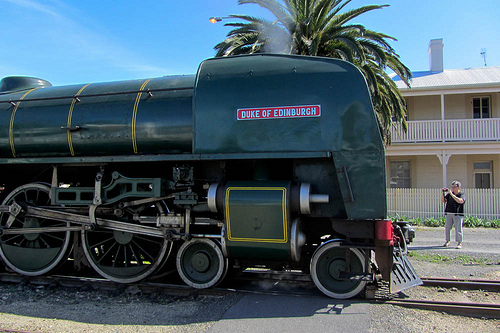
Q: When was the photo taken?
A: Daytime.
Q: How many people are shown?
A: One.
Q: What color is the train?
A: Green.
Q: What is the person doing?
A: Taking picture.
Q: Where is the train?
A: Tracks.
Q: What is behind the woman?
A: House.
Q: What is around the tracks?
A: Gravel.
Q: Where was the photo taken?
A: At a railway museum.